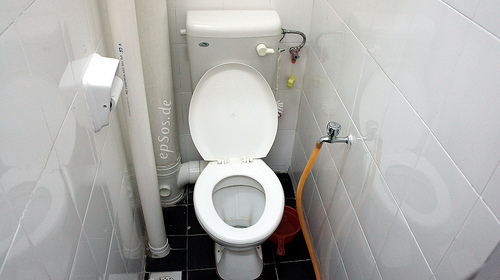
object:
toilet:
[179, 6, 295, 280]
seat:
[184, 155, 289, 249]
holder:
[78, 51, 127, 134]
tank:
[180, 7, 286, 108]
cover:
[181, 8, 287, 40]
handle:
[250, 40, 277, 59]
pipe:
[119, 0, 184, 213]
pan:
[270, 203, 303, 258]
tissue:
[108, 74, 127, 112]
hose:
[288, 142, 328, 279]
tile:
[10, 2, 88, 151]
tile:
[2, 23, 60, 224]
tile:
[11, 145, 89, 279]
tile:
[45, 87, 110, 236]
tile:
[365, 85, 433, 207]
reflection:
[348, 62, 456, 273]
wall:
[288, 0, 496, 280]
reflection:
[0, 79, 83, 279]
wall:
[1, 2, 154, 280]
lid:
[179, 58, 284, 164]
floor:
[135, 165, 319, 280]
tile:
[143, 203, 191, 238]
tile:
[144, 233, 191, 275]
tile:
[183, 203, 211, 237]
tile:
[182, 232, 218, 271]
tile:
[183, 266, 226, 279]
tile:
[271, 171, 296, 201]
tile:
[273, 258, 321, 280]